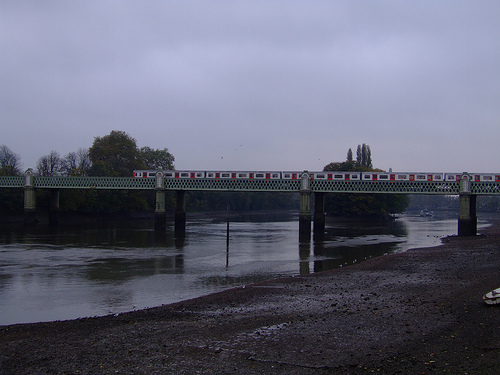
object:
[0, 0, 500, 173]
cloud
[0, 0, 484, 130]
water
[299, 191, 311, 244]
pillar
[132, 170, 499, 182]
red train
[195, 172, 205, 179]
white trim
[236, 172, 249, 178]
white trim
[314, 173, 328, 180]
white trim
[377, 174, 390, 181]
white trim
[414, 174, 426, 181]
white trim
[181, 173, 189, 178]
window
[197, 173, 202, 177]
window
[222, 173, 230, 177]
window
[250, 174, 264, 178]
window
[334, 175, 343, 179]
window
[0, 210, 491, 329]
water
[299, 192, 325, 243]
column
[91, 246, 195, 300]
podium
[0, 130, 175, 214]
trees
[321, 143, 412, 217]
trees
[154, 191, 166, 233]
pillar bridge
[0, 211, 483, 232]
shore line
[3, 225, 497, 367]
wet sand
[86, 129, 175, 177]
tree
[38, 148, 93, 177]
tree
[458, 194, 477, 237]
pillar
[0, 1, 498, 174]
sky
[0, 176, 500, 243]
bridge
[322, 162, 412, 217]
tree